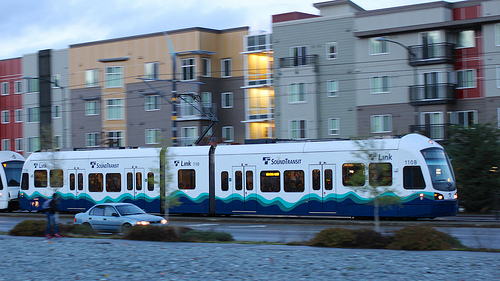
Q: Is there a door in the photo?
A: Yes, there is a door.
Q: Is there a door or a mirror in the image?
A: Yes, there is a door.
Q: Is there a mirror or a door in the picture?
A: Yes, there is a door.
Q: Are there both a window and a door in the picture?
A: Yes, there are both a door and a window.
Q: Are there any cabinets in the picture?
A: No, there are no cabinets.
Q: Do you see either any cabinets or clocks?
A: No, there are no cabinets or clocks.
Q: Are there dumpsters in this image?
A: No, there are no dumpsters.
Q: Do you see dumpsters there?
A: No, there are no dumpsters.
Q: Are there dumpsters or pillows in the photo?
A: No, there are no dumpsters or pillows.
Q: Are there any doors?
A: Yes, there is a door.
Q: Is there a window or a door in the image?
A: Yes, there is a door.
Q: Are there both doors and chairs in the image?
A: No, there is a door but no chairs.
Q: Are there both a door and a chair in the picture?
A: No, there is a door but no chairs.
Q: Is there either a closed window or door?
A: Yes, there is a closed door.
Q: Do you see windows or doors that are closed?
A: Yes, the door is closed.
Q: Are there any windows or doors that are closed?
A: Yes, the door is closed.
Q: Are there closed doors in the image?
A: Yes, there is a closed door.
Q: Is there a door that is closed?
A: Yes, there is a door that is closed.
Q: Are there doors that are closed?
A: Yes, there is a door that is closed.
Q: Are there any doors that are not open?
A: Yes, there is an closed door.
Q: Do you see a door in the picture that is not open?
A: Yes, there is an closed door.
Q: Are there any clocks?
A: No, there are no clocks.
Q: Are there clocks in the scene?
A: No, there are no clocks.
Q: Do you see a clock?
A: No, there are no clocks.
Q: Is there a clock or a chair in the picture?
A: No, there are no clocks or chairs.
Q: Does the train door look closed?
A: Yes, the door is closed.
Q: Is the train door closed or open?
A: The door is closed.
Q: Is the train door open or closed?
A: The door is closed.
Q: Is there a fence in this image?
A: No, there are no fences.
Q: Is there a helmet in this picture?
A: No, there are no helmets.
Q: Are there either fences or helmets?
A: No, there are no helmets or fences.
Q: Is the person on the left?
A: Yes, the person is on the left of the image.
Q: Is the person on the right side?
A: No, the person is on the left of the image.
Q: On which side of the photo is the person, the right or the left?
A: The person is on the left of the image.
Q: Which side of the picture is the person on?
A: The person is on the left of the image.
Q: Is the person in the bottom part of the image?
A: Yes, the person is in the bottom of the image.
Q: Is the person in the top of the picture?
A: No, the person is in the bottom of the image.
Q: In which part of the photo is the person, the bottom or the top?
A: The person is in the bottom of the image.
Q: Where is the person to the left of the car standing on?
A: The person is standing on the ground.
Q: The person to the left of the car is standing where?
A: The person is standing on the ground.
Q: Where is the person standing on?
A: The person is standing on the ground.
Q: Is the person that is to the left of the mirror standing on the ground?
A: Yes, the person is standing on the ground.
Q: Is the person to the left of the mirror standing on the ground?
A: Yes, the person is standing on the ground.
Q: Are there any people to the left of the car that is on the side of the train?
A: Yes, there is a person to the left of the car.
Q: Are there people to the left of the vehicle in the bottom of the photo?
A: Yes, there is a person to the left of the car.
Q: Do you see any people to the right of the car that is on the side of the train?
A: No, the person is to the left of the car.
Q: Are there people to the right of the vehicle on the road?
A: No, the person is to the left of the car.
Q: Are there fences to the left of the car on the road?
A: No, there is a person to the left of the car.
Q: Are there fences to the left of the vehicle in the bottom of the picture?
A: No, there is a person to the left of the car.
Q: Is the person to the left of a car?
A: Yes, the person is to the left of a car.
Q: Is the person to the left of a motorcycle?
A: No, the person is to the left of a car.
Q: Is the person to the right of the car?
A: No, the person is to the left of the car.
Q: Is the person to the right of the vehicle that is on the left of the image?
A: No, the person is to the left of the car.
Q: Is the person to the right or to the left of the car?
A: The person is to the left of the car.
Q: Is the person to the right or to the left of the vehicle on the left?
A: The person is to the left of the car.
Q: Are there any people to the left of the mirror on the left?
A: Yes, there is a person to the left of the mirror.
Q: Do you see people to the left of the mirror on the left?
A: Yes, there is a person to the left of the mirror.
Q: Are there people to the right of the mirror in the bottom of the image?
A: No, the person is to the left of the mirror.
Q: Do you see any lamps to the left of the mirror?
A: No, there is a person to the left of the mirror.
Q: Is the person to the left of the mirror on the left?
A: Yes, the person is to the left of the mirror.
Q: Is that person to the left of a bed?
A: No, the person is to the left of the mirror.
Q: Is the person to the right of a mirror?
A: No, the person is to the left of a mirror.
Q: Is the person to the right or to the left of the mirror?
A: The person is to the left of the mirror.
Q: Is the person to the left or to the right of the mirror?
A: The person is to the left of the mirror.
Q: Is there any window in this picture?
A: Yes, there are windows.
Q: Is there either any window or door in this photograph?
A: Yes, there are windows.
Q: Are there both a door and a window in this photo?
A: Yes, there are both a window and a door.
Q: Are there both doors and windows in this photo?
A: Yes, there are both windows and a door.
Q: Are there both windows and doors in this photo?
A: Yes, there are both windows and a door.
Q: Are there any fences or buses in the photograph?
A: No, there are no fences or buses.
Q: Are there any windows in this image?
A: Yes, there is a window.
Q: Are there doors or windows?
A: Yes, there is a window.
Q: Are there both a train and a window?
A: Yes, there are both a window and a train.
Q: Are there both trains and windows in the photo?
A: Yes, there are both a window and a train.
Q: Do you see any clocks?
A: No, there are no clocks.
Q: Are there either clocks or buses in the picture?
A: No, there are no clocks or buses.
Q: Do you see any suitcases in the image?
A: No, there are no suitcases.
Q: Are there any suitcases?
A: No, there are no suitcases.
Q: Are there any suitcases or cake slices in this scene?
A: No, there are no suitcases or cake slices.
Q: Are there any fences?
A: No, there are no fences.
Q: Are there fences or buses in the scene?
A: No, there are no fences or buses.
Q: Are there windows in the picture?
A: Yes, there is a window.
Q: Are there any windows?
A: Yes, there is a window.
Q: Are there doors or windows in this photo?
A: Yes, there is a window.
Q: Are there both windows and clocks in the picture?
A: No, there is a window but no clocks.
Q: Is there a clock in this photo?
A: No, there are no clocks.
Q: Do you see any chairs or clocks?
A: No, there are no clocks or chairs.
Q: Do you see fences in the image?
A: No, there are no fences.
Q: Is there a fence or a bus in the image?
A: No, there are no fences or buses.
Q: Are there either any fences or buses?
A: No, there are no fences or buses.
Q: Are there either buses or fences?
A: No, there are no fences or buses.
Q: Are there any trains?
A: Yes, there is a train.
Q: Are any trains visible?
A: Yes, there is a train.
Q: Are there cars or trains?
A: Yes, there is a train.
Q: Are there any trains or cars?
A: Yes, there is a train.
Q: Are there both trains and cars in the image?
A: Yes, there are both a train and a car.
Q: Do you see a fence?
A: No, there are no fences.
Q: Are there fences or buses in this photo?
A: No, there are no fences or buses.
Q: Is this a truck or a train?
A: This is a train.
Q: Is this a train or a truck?
A: This is a train.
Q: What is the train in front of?
A: The train is in front of the building.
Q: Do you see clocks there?
A: No, there are no clocks.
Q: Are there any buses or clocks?
A: No, there are no clocks or buses.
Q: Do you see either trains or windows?
A: Yes, there is a window.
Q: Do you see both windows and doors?
A: Yes, there are both a window and a door.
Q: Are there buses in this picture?
A: No, there are no buses.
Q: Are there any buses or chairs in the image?
A: No, there are no buses or chairs.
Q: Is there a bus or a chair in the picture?
A: No, there are no buses or chairs.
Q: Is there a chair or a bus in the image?
A: No, there are no buses or chairs.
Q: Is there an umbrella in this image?
A: No, there are no umbrellas.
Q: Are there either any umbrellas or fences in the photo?
A: No, there are no umbrellas or fences.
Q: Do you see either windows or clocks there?
A: Yes, there is a window.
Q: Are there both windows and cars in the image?
A: Yes, there are both a window and a car.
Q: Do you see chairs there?
A: No, there are no chairs.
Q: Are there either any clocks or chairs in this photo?
A: No, there are no chairs or clocks.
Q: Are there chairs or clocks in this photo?
A: No, there are no chairs or clocks.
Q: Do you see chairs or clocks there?
A: No, there are no chairs or clocks.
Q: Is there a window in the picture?
A: Yes, there is a window.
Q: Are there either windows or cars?
A: Yes, there is a window.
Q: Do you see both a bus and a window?
A: No, there is a window but no buses.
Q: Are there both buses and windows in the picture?
A: No, there is a window but no buses.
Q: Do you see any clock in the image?
A: No, there are no clocks.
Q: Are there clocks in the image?
A: No, there are no clocks.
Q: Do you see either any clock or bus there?
A: No, there are no clocks or buses.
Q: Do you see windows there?
A: Yes, there is a window.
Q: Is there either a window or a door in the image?
A: Yes, there is a window.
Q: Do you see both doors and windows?
A: Yes, there are both a window and a door.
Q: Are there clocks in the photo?
A: No, there are no clocks.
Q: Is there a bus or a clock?
A: No, there are no clocks or buses.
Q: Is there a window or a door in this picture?
A: Yes, there is a window.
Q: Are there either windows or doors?
A: Yes, there is a window.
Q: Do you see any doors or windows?
A: Yes, there is a window.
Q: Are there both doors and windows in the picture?
A: Yes, there are both a window and a door.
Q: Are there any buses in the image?
A: No, there are no buses.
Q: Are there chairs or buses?
A: No, there are no buses or chairs.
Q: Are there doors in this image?
A: Yes, there is a door.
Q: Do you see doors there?
A: Yes, there is a door.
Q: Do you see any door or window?
A: Yes, there is a door.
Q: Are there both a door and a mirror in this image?
A: Yes, there are both a door and a mirror.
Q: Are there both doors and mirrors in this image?
A: Yes, there are both a door and a mirror.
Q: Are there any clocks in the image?
A: No, there are no clocks.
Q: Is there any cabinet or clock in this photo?
A: No, there are no clocks or cabinets.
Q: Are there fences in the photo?
A: No, there are no fences.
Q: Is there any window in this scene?
A: Yes, there is a window.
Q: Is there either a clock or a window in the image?
A: Yes, there is a window.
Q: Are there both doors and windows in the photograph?
A: Yes, there are both a window and doors.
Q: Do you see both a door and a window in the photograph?
A: Yes, there are both a window and a door.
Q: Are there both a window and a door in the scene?
A: Yes, there are both a window and a door.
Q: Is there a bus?
A: No, there are no buses.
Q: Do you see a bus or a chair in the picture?
A: No, there are no buses or chairs.